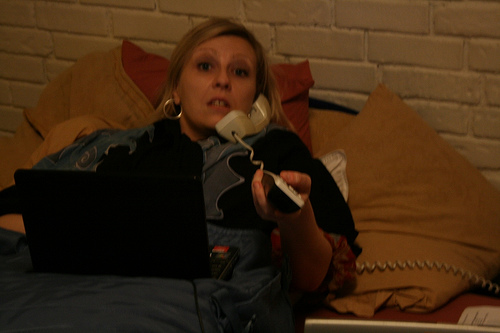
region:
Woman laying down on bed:
[38, 17, 418, 327]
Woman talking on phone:
[15, 12, 450, 297]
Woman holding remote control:
[11, 15, 426, 325]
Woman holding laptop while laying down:
[5, 15, 410, 330]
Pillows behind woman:
[95, 38, 486, 273]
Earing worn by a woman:
[157, 85, 184, 120]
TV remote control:
[250, 155, 308, 225]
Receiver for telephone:
[215, 90, 295, 145]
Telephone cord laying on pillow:
[357, 252, 495, 287]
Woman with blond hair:
[128, 15, 308, 157]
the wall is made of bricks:
[324, 20, 434, 80]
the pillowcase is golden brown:
[375, 165, 427, 193]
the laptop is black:
[71, 216, 127, 246]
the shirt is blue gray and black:
[213, 153, 245, 196]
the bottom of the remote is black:
[265, 175, 303, 217]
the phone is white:
[220, 105, 267, 125]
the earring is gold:
[158, 91, 210, 139]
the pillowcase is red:
[280, 75, 300, 116]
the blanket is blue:
[75, 292, 107, 304]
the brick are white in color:
[26, 17, 60, 50]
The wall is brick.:
[393, 18, 499, 83]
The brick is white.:
[395, 15, 499, 93]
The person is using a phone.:
[205, 90, 297, 166]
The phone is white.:
[208, 93, 280, 143]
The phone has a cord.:
[350, 241, 499, 298]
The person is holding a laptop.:
[8, 157, 248, 297]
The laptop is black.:
[12, 160, 249, 295]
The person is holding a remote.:
[222, 155, 313, 224]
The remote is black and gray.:
[237, 151, 326, 228]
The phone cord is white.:
[358, 251, 498, 303]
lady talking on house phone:
[131, 18, 289, 164]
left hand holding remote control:
[222, 140, 384, 291]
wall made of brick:
[20, 10, 482, 157]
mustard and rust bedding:
[27, 42, 472, 262]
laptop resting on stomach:
[15, 134, 300, 314]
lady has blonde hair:
[144, 15, 311, 112]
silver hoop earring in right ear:
[103, 26, 203, 133]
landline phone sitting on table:
[389, 256, 498, 329]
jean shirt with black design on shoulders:
[15, 98, 367, 309]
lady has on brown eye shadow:
[151, 23, 281, 128]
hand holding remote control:
[253, 164, 319, 224]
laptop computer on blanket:
[11, 165, 242, 285]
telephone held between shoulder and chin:
[217, 94, 270, 171]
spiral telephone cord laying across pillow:
[350, 246, 497, 301]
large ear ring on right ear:
[159, 91, 188, 122]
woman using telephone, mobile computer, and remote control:
[8, 17, 365, 295]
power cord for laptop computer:
[176, 275, 218, 330]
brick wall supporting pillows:
[321, 8, 498, 170]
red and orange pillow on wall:
[32, 21, 157, 133]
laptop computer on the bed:
[302, 292, 494, 328]